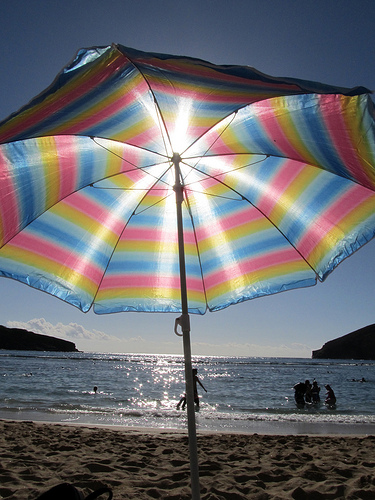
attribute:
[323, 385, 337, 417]
people — playing, together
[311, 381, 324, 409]
people — playing, together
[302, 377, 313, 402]
people — together, playing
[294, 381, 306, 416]
people — playing, together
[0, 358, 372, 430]
water — choppy, shiny, blue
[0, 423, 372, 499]
sand — brown, gray, trampled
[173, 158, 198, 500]
pole — adjustable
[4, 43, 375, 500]
umbrella — pink, blue, yellow, white, red, tall, striped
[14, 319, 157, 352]
clouds — puffy, lonely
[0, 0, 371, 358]
sky — clear, blue, dark blue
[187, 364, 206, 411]
man — playing, lone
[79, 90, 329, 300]
sun — shining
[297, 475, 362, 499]
rocky cliff — black